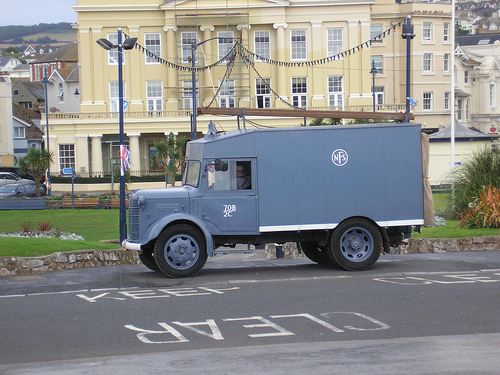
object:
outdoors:
[0, 163, 500, 375]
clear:
[124, 306, 390, 344]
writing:
[371, 268, 499, 287]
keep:
[76, 286, 241, 303]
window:
[145, 80, 163, 117]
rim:
[164, 234, 201, 271]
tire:
[153, 221, 209, 278]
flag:
[118, 145, 131, 172]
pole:
[118, 30, 128, 244]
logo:
[331, 148, 349, 166]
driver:
[207, 161, 252, 190]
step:
[399, 234, 500, 254]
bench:
[59, 197, 101, 210]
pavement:
[0, 253, 500, 375]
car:
[0, 172, 46, 197]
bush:
[453, 183, 500, 230]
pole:
[451, 0, 455, 210]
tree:
[13, 144, 56, 199]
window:
[181, 32, 198, 63]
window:
[254, 31, 271, 62]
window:
[327, 28, 344, 58]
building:
[0, 0, 500, 194]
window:
[110, 80, 126, 116]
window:
[329, 77, 343, 108]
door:
[201, 158, 258, 236]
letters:
[332, 148, 349, 167]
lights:
[96, 37, 139, 51]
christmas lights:
[121, 18, 406, 110]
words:
[75, 286, 390, 345]